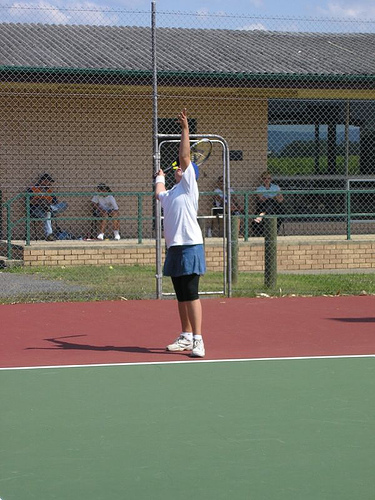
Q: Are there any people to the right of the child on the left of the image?
A: Yes, there is a person to the right of the child.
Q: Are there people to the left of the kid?
A: No, the person is to the right of the kid.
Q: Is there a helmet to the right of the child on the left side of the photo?
A: No, there is a person to the right of the child.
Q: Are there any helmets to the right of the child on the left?
A: No, there is a person to the right of the child.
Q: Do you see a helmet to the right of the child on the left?
A: No, there is a person to the right of the child.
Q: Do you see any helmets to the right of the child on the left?
A: No, there is a person to the right of the child.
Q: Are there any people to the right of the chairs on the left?
A: Yes, there is a person to the right of the chairs.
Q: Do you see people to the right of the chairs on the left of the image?
A: Yes, there is a person to the right of the chairs.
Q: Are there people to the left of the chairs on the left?
A: No, the person is to the right of the chairs.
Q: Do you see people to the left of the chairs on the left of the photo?
A: No, the person is to the right of the chairs.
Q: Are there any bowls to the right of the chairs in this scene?
A: No, there is a person to the right of the chairs.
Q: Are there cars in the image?
A: No, there are no cars.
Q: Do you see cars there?
A: No, there are no cars.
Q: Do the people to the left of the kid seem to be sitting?
A: Yes, the people are sitting.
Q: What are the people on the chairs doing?
A: The people are sitting.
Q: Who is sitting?
A: The people are sitting.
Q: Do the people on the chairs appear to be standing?
A: No, the people are sitting.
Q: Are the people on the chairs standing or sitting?
A: The people are sitting.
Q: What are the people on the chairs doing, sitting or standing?
A: The people are sitting.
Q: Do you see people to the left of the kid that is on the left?
A: Yes, there are people to the left of the child.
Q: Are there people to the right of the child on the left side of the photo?
A: No, the people are to the left of the child.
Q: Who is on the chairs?
A: The people are on the chairs.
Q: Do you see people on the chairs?
A: Yes, there are people on the chairs.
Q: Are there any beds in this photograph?
A: No, there are no beds.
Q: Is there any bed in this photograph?
A: No, there are no beds.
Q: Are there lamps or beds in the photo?
A: No, there are no beds or lamps.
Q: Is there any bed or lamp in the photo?
A: No, there are no beds or lamps.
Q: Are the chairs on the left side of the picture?
A: Yes, the chairs are on the left of the image.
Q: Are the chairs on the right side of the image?
A: No, the chairs are on the left of the image.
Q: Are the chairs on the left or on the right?
A: The chairs are on the left of the image.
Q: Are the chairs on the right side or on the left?
A: The chairs are on the left of the image.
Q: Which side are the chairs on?
A: The chairs are on the left of the image.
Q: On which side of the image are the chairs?
A: The chairs are on the left of the image.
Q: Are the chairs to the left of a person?
A: Yes, the chairs are to the left of a person.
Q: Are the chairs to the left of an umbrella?
A: No, the chairs are to the left of a person.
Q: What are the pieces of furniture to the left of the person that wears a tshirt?
A: The pieces of furniture are chairs.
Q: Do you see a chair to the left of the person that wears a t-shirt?
A: Yes, there are chairs to the left of the person.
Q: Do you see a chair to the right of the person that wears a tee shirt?
A: No, the chairs are to the left of the person.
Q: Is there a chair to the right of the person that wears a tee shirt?
A: No, the chairs are to the left of the person.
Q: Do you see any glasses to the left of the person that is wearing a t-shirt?
A: No, there are chairs to the left of the person.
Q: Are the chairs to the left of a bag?
A: No, the chairs are to the left of a person.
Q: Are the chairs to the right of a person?
A: No, the chairs are to the left of a person.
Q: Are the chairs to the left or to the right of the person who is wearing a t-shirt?
A: The chairs are to the left of the person.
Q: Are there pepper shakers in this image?
A: No, there are no pepper shakers.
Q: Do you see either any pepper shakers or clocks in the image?
A: No, there are no pepper shakers or clocks.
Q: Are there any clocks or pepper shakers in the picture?
A: No, there are no pepper shakers or clocks.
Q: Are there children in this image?
A: Yes, there is a child.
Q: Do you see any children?
A: Yes, there is a child.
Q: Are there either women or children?
A: Yes, there is a child.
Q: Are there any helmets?
A: No, there are no helmets.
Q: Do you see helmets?
A: No, there are no helmets.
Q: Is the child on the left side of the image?
A: Yes, the child is on the left of the image.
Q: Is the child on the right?
A: No, the child is on the left of the image.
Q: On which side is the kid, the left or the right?
A: The kid is on the left of the image.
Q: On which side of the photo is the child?
A: The child is on the left of the image.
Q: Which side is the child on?
A: The child is on the left of the image.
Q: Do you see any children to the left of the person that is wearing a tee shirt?
A: Yes, there is a child to the left of the person.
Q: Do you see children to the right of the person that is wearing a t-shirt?
A: No, the child is to the left of the person.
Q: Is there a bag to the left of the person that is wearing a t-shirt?
A: No, there is a child to the left of the person.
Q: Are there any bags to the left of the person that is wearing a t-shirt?
A: No, there is a child to the left of the person.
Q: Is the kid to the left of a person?
A: Yes, the kid is to the left of a person.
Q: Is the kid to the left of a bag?
A: No, the kid is to the left of a person.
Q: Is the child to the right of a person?
A: No, the child is to the left of a person.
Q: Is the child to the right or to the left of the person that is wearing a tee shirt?
A: The child is to the left of the person.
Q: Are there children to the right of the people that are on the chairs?
A: Yes, there is a child to the right of the people.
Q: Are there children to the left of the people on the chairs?
A: No, the child is to the right of the people.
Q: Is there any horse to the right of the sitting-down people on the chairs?
A: No, there is a child to the right of the people.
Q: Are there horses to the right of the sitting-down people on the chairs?
A: No, there is a child to the right of the people.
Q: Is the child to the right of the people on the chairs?
A: Yes, the child is to the right of the people.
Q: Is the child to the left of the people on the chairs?
A: No, the child is to the right of the people.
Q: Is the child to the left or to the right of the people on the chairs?
A: The child is to the right of the people.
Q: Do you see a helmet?
A: No, there are no helmets.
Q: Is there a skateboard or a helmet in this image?
A: No, there are no helmets or skateboards.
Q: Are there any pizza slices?
A: No, there are no pizza slices.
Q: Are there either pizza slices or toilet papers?
A: No, there are no pizza slices or toilet papers.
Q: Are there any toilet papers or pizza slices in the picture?
A: No, there are no pizza slices or toilet papers.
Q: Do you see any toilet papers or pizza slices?
A: No, there are no pizza slices or toilet papers.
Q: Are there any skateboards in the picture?
A: No, there are no skateboards.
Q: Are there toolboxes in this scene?
A: No, there are no toolboxes.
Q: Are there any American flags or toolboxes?
A: No, there are no toolboxes or American flags.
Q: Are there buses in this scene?
A: No, there are no buses.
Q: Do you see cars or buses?
A: No, there are no buses or cars.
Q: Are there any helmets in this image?
A: No, there are no helmets.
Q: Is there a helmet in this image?
A: No, there are no helmets.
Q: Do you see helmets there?
A: No, there are no helmets.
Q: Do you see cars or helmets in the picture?
A: No, there are no helmets or cars.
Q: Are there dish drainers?
A: No, there are no dish drainers.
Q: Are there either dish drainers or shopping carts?
A: No, there are no dish drainers or shopping carts.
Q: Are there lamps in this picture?
A: No, there are no lamps.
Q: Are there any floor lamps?
A: No, there are no floor lamps.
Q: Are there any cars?
A: No, there are no cars.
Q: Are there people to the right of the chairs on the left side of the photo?
A: Yes, there is a person to the right of the chairs.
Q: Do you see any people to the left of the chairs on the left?
A: No, the person is to the right of the chairs.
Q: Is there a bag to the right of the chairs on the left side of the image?
A: No, there is a person to the right of the chairs.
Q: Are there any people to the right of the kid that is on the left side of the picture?
A: Yes, there is a person to the right of the kid.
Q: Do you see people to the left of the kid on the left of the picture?
A: No, the person is to the right of the kid.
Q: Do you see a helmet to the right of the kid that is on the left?
A: No, there is a person to the right of the child.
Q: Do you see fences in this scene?
A: Yes, there is a fence.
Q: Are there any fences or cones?
A: Yes, there is a fence.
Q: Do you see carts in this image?
A: No, there are no carts.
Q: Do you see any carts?
A: No, there are no carts.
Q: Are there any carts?
A: No, there are no carts.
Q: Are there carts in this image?
A: No, there are no carts.